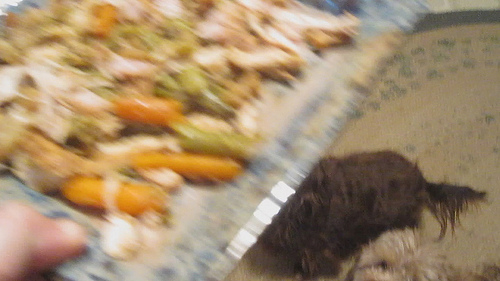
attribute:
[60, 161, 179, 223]
food — yellow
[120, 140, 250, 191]
food — yellow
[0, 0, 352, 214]
chicken — cut up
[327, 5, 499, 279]
rug — tan, green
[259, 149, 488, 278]
dog — dark, brown, tan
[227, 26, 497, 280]
rug — oval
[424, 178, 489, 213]
tail — brown, furry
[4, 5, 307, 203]
food — blurry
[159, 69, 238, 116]
brocolli — blurry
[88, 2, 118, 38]
carrot — blurry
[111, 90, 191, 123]
carrot — blurry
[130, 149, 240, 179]
carrot — blurry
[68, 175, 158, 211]
carrot — blurry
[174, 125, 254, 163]
bean — green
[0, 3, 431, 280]
tray — silver